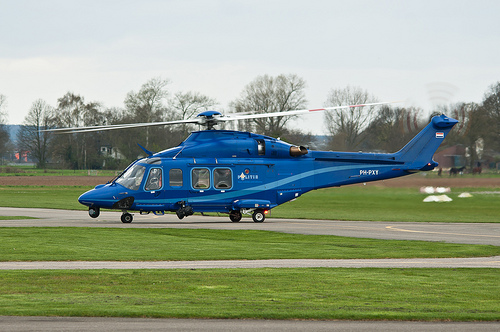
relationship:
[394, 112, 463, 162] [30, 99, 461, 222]
tail of helicopter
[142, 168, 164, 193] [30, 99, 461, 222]
window on helicopter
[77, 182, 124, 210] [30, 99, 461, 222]
tip of helicopter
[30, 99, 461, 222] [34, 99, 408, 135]
helicopter has propeller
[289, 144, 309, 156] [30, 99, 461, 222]
exhaust on helicopter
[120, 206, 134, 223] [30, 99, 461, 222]
landing gear on helicopter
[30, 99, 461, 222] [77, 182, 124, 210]
helicopter has tip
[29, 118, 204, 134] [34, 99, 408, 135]
rotor on propeller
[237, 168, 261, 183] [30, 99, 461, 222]
decal on helicopter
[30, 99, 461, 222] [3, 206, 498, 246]
helicopter on asphalt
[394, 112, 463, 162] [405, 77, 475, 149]
tail has rotor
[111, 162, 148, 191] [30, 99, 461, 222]
windshield on helicopter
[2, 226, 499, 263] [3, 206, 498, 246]
grass next to asphalt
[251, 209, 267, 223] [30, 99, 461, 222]
wheel on helicopter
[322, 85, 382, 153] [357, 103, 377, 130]
tree has branch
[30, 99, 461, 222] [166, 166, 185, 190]
helicopter has window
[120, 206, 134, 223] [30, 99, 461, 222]
landing gear under helicopter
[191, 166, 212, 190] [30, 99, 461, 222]
window on helicopter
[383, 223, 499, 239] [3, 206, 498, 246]
line on asphalt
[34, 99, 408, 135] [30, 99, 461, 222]
propeller on top helicopter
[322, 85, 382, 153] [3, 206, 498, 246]
tree near asphalt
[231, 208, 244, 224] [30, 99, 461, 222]
wheel on helicopter